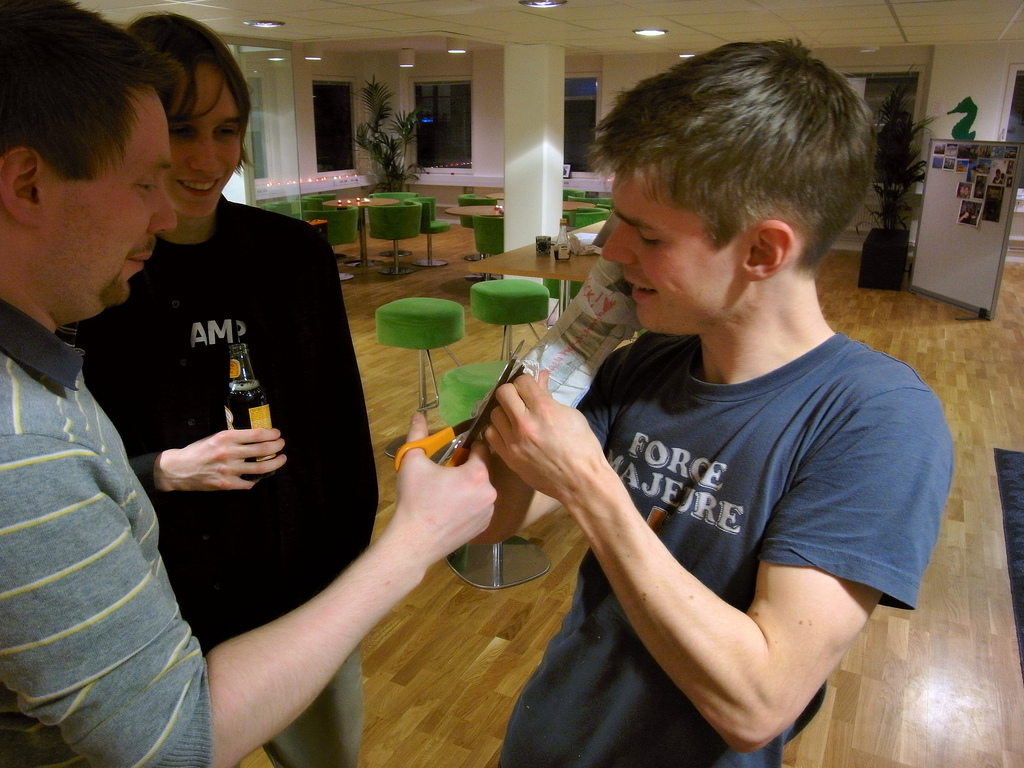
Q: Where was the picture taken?
A: In the family room.